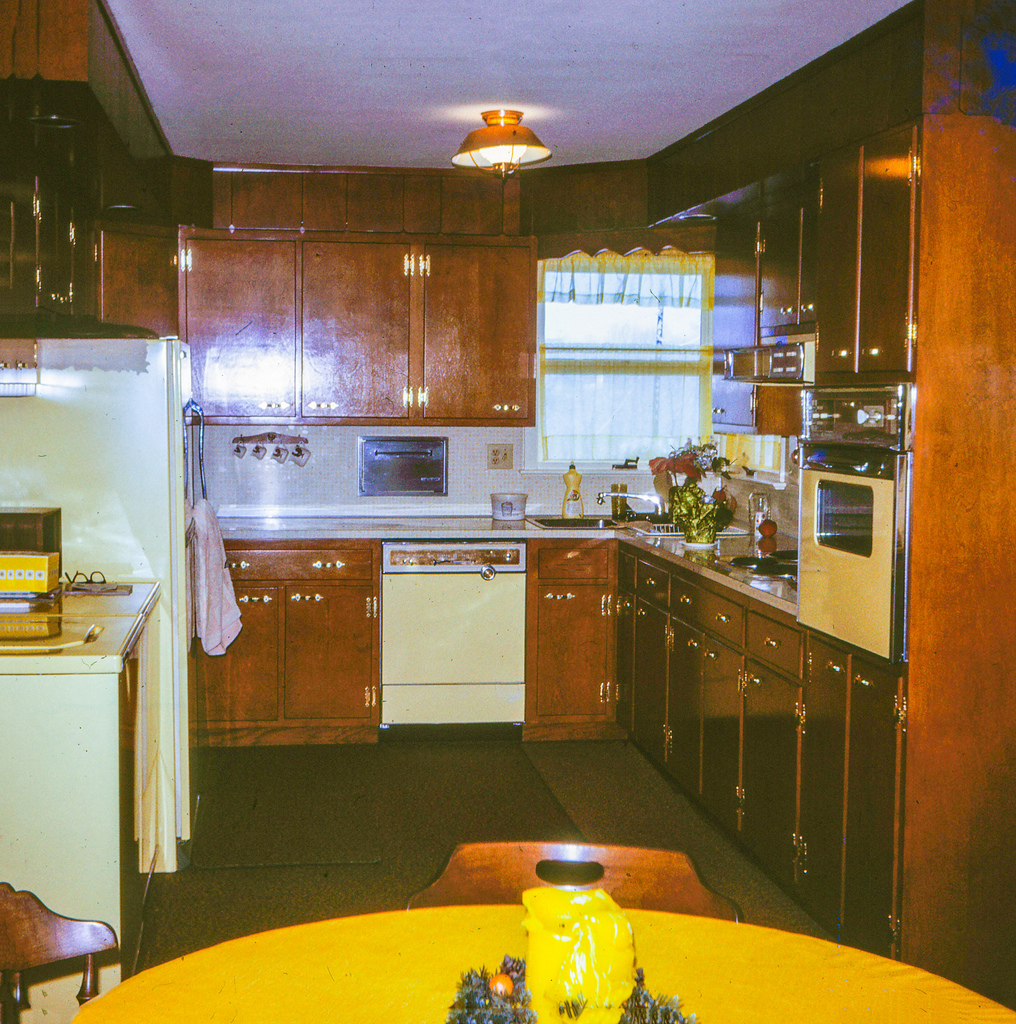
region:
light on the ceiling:
[425, 58, 593, 227]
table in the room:
[182, 874, 472, 1022]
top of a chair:
[421, 790, 735, 922]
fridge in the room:
[2, 308, 306, 879]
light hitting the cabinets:
[211, 283, 357, 419]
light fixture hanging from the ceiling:
[433, 97, 565, 176]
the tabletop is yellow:
[56, 904, 1015, 1021]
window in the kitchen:
[532, 251, 719, 483]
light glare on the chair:
[50, 920, 109, 949]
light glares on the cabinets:
[191, 313, 378, 416]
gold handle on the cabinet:
[287, 583, 333, 607]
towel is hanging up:
[198, 489, 248, 661]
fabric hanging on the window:
[536, 261, 707, 314]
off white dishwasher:
[371, 535, 553, 738]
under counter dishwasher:
[381, 534, 526, 727]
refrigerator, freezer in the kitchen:
[5, 329, 193, 877]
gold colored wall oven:
[801, 390, 899, 664]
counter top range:
[714, 535, 812, 594]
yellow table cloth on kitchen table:
[71, 903, 1012, 1022]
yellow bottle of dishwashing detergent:
[559, 460, 592, 519]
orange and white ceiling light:
[455, 101, 560, 189]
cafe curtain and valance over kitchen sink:
[540, 267, 709, 455]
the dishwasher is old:
[381, 536, 530, 746]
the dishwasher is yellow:
[381, 536, 526, 745]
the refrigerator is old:
[0, 331, 210, 869]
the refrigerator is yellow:
[1, 340, 212, 871]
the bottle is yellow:
[558, 462, 585, 518]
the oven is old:
[791, 382, 917, 662]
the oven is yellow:
[789, 375, 916, 662]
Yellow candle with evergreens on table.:
[448, 863, 686, 1021]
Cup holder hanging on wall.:
[223, 427, 320, 471]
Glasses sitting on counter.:
[59, 565, 114, 588]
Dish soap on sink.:
[552, 462, 591, 522]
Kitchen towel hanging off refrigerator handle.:
[184, 491, 244, 659]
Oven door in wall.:
[354, 429, 454, 500]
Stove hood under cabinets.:
[717, 330, 818, 392]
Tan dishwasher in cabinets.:
[377, 541, 532, 729]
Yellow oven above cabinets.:
[796, 384, 912, 661]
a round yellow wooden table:
[63, 894, 1013, 1018]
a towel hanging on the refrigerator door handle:
[192, 496, 245, 661]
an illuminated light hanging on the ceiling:
[453, 106, 550, 187]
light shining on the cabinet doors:
[185, 327, 376, 421]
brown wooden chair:
[407, 835, 740, 923]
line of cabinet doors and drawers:
[617, 539, 897, 952]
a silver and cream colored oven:
[801, 382, 912, 666]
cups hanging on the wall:
[228, 431, 313, 470]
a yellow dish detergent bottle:
[562, 459, 585, 522]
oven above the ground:
[305, 515, 598, 753]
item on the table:
[476, 823, 719, 1008]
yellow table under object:
[243, 887, 427, 1021]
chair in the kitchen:
[2, 845, 189, 1003]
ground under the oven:
[227, 764, 427, 893]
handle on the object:
[687, 582, 759, 647]